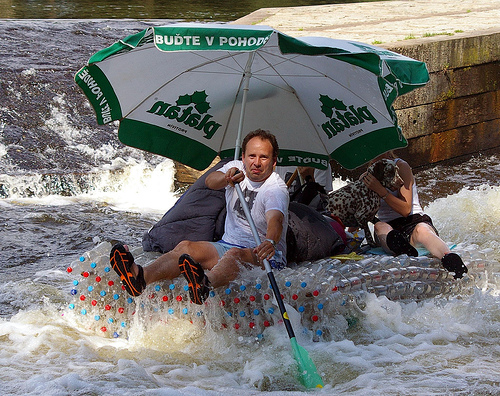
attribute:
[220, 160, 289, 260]
shirt — white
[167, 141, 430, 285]
people — rafting, sitting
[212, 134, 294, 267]
man — rafting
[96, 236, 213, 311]
shoes — black, orange, sandals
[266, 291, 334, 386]
paddle — green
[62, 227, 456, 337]
raft — polka dotted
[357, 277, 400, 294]
bottles — clear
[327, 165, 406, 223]
dog — brown, white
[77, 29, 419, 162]
umbrella — green, white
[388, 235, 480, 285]
black shoes — flip flops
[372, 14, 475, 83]
bricks — brown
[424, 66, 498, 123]
moss — green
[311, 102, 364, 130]
letters — green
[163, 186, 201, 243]
sleeping bag — gray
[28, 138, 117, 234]
water — rough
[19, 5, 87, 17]
water — calm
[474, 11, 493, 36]
wall — brick, bricks, tan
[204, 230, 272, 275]
shorts — blue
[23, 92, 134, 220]
waterfall — small